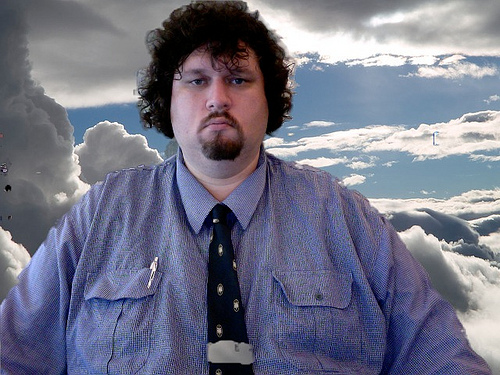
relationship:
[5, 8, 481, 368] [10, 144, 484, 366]
man wearing shirt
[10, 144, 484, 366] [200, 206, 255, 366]
shirt in tie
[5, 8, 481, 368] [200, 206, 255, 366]
man in tie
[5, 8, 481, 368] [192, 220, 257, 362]
man in a tie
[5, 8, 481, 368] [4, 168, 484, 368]
man wearing a shirt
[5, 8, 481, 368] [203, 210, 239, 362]
man in a tie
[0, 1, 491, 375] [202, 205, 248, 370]
man in tie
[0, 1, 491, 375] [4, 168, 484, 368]
man wearing a shirt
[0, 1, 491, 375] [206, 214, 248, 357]
man in a tie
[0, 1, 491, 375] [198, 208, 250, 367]
man in a tie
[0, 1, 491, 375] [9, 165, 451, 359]
man wearing a shirt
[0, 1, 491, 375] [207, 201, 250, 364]
man in a tie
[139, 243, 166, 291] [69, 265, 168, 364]
pen tucked into pocket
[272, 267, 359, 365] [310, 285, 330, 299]
pocket with button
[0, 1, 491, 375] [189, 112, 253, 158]
man with goatee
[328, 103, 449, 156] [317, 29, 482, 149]
clouds in sky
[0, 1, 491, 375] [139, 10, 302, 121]
man with hair